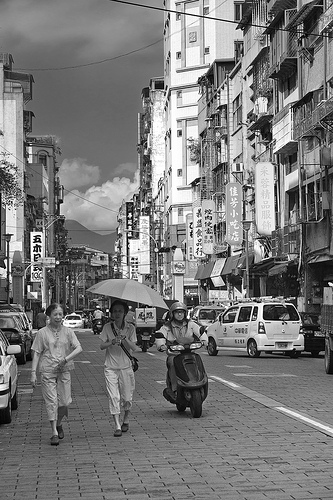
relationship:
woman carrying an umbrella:
[94, 300, 143, 440] [83, 276, 171, 344]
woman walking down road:
[30, 302, 82, 444] [0, 324, 333, 497]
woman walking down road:
[99, 300, 137, 436] [0, 324, 333, 497]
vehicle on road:
[0, 312, 34, 363] [0, 324, 331, 497]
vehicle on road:
[0, 329, 21, 424] [0, 324, 331, 497]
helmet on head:
[31, 231, 43, 284] [167, 294, 185, 326]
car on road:
[200, 303, 309, 355] [78, 341, 308, 475]